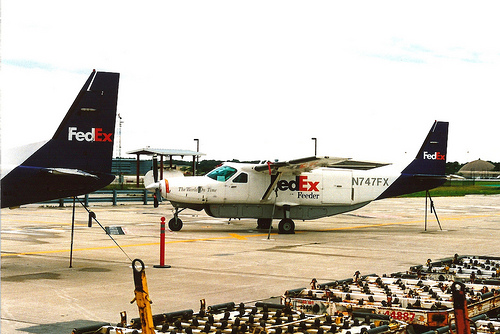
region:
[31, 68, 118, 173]
tail of a plane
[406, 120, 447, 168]
tail of a plane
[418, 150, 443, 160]
logo on the tail of a plane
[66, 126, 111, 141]
logo on the tail of a plane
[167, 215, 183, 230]
front wheel of a plane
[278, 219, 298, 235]
back wheel of a plane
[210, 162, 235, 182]
cockpit window of a plane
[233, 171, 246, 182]
side window of a plane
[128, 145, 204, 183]
a metal roof and poles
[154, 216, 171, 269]
an orange safety pillar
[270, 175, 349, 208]
Blue and red writing on side of plane.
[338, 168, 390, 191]
Gray letters and numbers on side of plane.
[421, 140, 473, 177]
Fed ex on tail of plane.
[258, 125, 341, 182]
Wing on side of plane.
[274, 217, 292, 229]
Black wing on bottom of plane.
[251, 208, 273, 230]
Black wing on bottom of plane.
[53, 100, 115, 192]
Blue tail on back of plane.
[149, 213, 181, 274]
Orange cone on pavement.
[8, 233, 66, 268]
Yellow line marking pavement.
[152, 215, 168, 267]
an orange traffic safety cone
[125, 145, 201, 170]
a small storage building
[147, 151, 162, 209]
the propeller on a single engine plane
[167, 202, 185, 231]
the front landing gear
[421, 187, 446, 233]
tie down straps to secure the plane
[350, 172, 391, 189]
the planes identification numbers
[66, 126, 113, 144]
the businesses brand name logo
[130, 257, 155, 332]
a trailer hitch attachment neck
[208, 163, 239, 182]
the planes front windshield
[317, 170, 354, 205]
the cargo loading door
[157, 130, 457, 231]
this is a plane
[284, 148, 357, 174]
this is the wing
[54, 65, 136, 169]
this is the tail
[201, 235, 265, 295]
this is the runway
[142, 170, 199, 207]
this is the front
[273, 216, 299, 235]
this is the wheel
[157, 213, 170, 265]
this is a pole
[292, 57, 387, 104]
this is the sky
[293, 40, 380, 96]
the sky is white in color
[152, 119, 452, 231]
a FedEx prop plane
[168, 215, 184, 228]
the nose wheel of a plane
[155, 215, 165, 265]
an orange post on the tarmac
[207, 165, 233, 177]
a front window on a plane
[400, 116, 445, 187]
the tail of a plane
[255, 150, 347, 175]
the wing of a plane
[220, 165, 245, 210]
the door of a plane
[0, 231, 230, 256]
a yellow stripe painted on the tarmac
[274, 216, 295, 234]
a wheel under a wing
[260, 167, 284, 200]
a support under the wing of a plane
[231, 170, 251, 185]
Window on a plane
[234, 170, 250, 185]
Window on a white plane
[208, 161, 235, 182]
Window on a plane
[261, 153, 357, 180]
Wing of a plane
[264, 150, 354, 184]
Wing of a plane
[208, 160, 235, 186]
Window of a plane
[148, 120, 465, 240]
Fed Ex on the runway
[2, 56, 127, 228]
Fed Ex on the runway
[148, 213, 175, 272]
safety stand on the runway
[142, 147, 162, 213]
propeller on the airplane